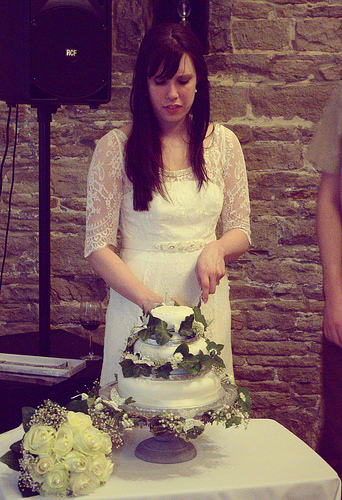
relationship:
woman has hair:
[82, 20, 252, 384] [122, 21, 211, 211]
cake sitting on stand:
[113, 299, 226, 407] [97, 379, 251, 465]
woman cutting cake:
[82, 20, 252, 384] [113, 299, 226, 407]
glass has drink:
[76, 296, 101, 362] [78, 319, 103, 331]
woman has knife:
[82, 20, 252, 384] [195, 288, 205, 308]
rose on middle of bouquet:
[22, 424, 58, 456] [0, 398, 124, 499]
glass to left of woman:
[76, 296, 101, 362] [82, 20, 252, 384]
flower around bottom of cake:
[156, 412, 185, 435] [113, 299, 226, 407]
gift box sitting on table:
[0, 351, 88, 387] [0, 327, 104, 434]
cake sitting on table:
[113, 299, 226, 407] [0, 417, 342, 499]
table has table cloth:
[0, 327, 104, 434] [1, 417, 340, 499]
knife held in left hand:
[195, 288, 205, 308] [195, 241, 227, 304]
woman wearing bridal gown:
[82, 20, 252, 384] [82, 122, 253, 382]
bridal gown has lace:
[82, 122, 253, 382] [82, 121, 253, 257]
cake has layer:
[113, 299, 226, 407] [147, 304, 195, 336]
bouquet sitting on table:
[0, 398, 124, 499] [0, 417, 342, 499]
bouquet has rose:
[0, 398, 124, 499] [73, 424, 103, 457]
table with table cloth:
[0, 327, 104, 434] [1, 417, 340, 499]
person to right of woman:
[304, 80, 341, 479] [82, 20, 252, 384]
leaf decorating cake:
[178, 314, 197, 340] [113, 299, 226, 407]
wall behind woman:
[0, 1, 341, 479] [82, 20, 252, 384]